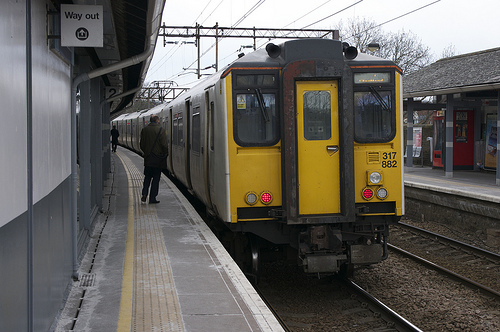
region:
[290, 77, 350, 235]
yellow metal door on front of train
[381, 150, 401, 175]
black numbers on front of train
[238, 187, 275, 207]
headlights on front of train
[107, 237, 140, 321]
yellow stripe painted on train platform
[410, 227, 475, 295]
brown metal train tracks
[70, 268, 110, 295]
small metal grating on train platform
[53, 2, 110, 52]
white sign hanging beside train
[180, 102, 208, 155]
window on side of train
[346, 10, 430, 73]
trees with no leaves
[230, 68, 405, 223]
a yellow rear door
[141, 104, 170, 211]
a man waits for the train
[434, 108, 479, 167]
a red vending machine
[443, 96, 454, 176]
a grey roof support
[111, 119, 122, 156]
s person walks away dressed in black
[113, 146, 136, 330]
a yellow line along the brick path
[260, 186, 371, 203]
red rear lights are lit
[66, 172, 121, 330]
drain along the wall for the rain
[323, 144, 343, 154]
a silver colored door latch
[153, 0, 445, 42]
overhead power lines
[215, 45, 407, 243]
the back of a train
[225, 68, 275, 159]
the back window of a train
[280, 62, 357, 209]
the back door of a train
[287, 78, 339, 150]
a window on the back door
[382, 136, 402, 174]
the number of a train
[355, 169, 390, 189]
the rear light of a train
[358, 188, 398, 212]
a pair of headlights on a train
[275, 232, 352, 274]
the stairs of a train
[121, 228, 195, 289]
the safety line at a station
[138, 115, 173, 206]
a man waiting for the train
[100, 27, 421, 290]
A train on the train tracks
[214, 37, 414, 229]
A back view of a train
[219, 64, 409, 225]
Back of the train is yellow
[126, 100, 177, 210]
A back view of a man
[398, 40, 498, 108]
The roof is gray in color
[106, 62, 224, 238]
The side of the train is silver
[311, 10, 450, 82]
Bare trees in the background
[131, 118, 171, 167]
Man is wearing a olive colored coat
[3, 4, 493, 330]
Photo was taken in the daytime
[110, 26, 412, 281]
A train pulling in to a station